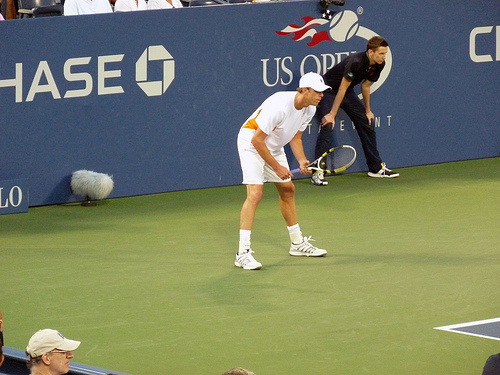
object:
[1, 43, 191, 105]
chase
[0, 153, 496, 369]
court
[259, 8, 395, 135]
logo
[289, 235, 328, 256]
shoe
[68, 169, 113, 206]
bag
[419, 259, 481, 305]
ground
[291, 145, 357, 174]
racket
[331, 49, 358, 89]
microphone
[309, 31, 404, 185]
boy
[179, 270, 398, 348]
floor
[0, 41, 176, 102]
sponsorship logo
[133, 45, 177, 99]
logo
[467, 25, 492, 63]
letter c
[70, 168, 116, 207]
mike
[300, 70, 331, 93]
cap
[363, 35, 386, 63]
head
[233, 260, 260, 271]
sole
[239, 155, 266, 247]
legs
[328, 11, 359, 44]
ball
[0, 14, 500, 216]
poster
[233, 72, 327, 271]
man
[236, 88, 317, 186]
outfit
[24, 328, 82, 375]
man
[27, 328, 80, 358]
cap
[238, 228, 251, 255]
sock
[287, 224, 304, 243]
sock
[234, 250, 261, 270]
shoe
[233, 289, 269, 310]
part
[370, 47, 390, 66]
face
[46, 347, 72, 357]
glasses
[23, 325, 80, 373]
head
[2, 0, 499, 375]
tennis match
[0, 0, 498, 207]
wall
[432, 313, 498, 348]
stripe